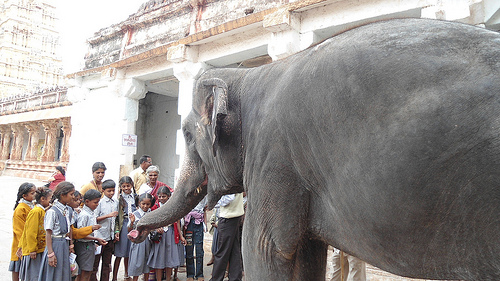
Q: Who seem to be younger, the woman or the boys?
A: The boys are younger than the woman.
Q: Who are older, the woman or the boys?
A: The woman are older than the boys.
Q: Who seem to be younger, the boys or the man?
A: The boys are younger than the man.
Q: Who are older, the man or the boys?
A: The man are older than the boys.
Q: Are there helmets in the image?
A: No, there are no helmets.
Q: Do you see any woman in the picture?
A: Yes, there is a woman.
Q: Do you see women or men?
A: Yes, there is a woman.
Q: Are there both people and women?
A: Yes, there are both a woman and a person.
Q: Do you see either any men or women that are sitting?
A: Yes, the woman is sitting.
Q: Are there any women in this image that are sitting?
A: Yes, there is a woman that is sitting.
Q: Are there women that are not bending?
A: Yes, there is a woman that is sitting.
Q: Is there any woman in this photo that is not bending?
A: Yes, there is a woman that is sitting.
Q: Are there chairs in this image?
A: No, there are no chairs.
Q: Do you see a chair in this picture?
A: No, there are no chairs.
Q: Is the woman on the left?
A: Yes, the woman is on the left of the image.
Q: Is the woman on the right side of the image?
A: No, the woman is on the left of the image.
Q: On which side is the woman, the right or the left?
A: The woman is on the left of the image.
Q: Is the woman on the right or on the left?
A: The woman is on the left of the image.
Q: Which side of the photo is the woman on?
A: The woman is on the left of the image.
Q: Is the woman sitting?
A: Yes, the woman is sitting.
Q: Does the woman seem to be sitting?
A: Yes, the woman is sitting.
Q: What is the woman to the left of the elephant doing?
A: The woman is sitting.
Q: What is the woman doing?
A: The woman is sitting.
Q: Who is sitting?
A: The woman is sitting.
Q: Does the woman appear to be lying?
A: No, the woman is sitting.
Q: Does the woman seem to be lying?
A: No, the woman is sitting.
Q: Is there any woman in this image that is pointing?
A: No, there is a woman but she is sitting.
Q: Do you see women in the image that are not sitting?
A: No, there is a woman but she is sitting.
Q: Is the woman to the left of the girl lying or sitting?
A: The woman is sitting.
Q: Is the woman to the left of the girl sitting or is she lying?
A: The woman is sitting.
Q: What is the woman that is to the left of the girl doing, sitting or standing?
A: The woman is sitting.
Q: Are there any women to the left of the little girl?
A: Yes, there is a woman to the left of the girl.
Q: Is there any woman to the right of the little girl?
A: No, the woman is to the left of the girl.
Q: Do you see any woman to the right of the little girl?
A: No, the woman is to the left of the girl.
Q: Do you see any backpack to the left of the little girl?
A: No, there is a woman to the left of the girl.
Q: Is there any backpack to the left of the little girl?
A: No, there is a woman to the left of the girl.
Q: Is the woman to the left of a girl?
A: Yes, the woman is to the left of a girl.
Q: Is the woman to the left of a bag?
A: No, the woman is to the left of a girl.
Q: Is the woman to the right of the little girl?
A: No, the woman is to the left of the girl.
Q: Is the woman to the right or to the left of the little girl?
A: The woman is to the left of the girl.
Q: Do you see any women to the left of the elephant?
A: Yes, there is a woman to the left of the elephant.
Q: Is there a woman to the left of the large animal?
A: Yes, there is a woman to the left of the elephant.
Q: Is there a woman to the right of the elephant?
A: No, the woman is to the left of the elephant.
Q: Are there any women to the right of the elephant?
A: No, the woman is to the left of the elephant.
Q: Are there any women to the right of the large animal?
A: No, the woman is to the left of the elephant.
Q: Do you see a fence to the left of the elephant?
A: No, there is a woman to the left of the elephant.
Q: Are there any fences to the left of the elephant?
A: No, there is a woman to the left of the elephant.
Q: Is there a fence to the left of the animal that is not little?
A: No, there is a woman to the left of the elephant.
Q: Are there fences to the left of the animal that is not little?
A: No, there is a woman to the left of the elephant.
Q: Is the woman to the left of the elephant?
A: Yes, the woman is to the left of the elephant.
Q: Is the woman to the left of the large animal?
A: Yes, the woman is to the left of the elephant.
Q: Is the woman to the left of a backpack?
A: No, the woman is to the left of the elephant.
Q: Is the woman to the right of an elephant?
A: No, the woman is to the left of an elephant.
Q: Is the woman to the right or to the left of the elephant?
A: The woman is to the left of the elephant.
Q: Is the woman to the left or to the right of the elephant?
A: The woman is to the left of the elephant.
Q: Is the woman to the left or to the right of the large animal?
A: The woman is to the left of the elephant.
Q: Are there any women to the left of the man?
A: Yes, there is a woman to the left of the man.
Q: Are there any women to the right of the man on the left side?
A: No, the woman is to the left of the man.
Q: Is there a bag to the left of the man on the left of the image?
A: No, there is a woman to the left of the man.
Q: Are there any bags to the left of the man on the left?
A: No, there is a woman to the left of the man.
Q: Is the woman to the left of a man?
A: Yes, the woman is to the left of a man.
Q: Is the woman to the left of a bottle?
A: No, the woman is to the left of a man.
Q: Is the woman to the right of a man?
A: No, the woman is to the left of a man.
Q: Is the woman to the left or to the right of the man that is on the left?
A: The woman is to the left of the man.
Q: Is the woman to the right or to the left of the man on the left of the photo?
A: The woman is to the left of the man.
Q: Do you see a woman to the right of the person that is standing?
A: Yes, there is a woman to the right of the person.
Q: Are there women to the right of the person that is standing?
A: Yes, there is a woman to the right of the person.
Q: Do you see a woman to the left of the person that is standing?
A: No, the woman is to the right of the person.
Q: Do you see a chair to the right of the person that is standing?
A: No, there is a woman to the right of the person.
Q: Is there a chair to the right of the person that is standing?
A: No, there is a woman to the right of the person.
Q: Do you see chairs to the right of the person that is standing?
A: No, there is a woman to the right of the person.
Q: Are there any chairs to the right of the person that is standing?
A: No, there is a woman to the right of the person.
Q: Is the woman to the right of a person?
A: Yes, the woman is to the right of a person.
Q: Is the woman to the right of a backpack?
A: No, the woman is to the right of a person.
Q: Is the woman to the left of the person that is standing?
A: No, the woman is to the right of the person.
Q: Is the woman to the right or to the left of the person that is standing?
A: The woman is to the right of the person.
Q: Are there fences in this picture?
A: No, there are no fences.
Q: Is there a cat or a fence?
A: No, there are no fences or cats.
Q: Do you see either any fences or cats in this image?
A: No, there are no fences or cats.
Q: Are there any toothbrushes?
A: No, there are no toothbrushes.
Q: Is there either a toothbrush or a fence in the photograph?
A: No, there are no toothbrushes or fences.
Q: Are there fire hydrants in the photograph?
A: No, there are no fire hydrants.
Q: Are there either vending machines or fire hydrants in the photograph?
A: No, there are no fire hydrants or vending machines.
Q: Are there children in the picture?
A: Yes, there are children.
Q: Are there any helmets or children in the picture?
A: Yes, there are children.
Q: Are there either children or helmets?
A: Yes, there are children.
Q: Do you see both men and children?
A: Yes, there are both children and a man.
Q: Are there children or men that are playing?
A: Yes, the children are playing.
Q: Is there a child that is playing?
A: Yes, there are children that are playing.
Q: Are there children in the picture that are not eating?
A: Yes, there are children that are playing.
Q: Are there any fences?
A: No, there are no fences.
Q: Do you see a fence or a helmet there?
A: No, there are no fences or helmets.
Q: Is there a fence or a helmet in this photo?
A: No, there are no fences or helmets.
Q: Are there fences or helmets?
A: No, there are no fences or helmets.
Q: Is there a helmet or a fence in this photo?
A: No, there are no fences or helmets.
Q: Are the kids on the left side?
A: Yes, the kids are on the left of the image.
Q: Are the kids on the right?
A: No, the kids are on the left of the image.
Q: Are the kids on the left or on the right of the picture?
A: The kids are on the left of the image.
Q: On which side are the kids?
A: The kids are on the left of the image.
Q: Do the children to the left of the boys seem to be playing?
A: Yes, the children are playing.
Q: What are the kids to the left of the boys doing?
A: The kids are playing.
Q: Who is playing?
A: The kids are playing.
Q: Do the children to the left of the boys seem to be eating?
A: No, the children are playing.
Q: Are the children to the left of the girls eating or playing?
A: The children are playing.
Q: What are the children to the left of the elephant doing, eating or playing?
A: The children are playing.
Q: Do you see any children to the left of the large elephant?
A: Yes, there are children to the left of the elephant.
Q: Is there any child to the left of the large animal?
A: Yes, there are children to the left of the elephant.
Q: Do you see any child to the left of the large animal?
A: Yes, there are children to the left of the elephant.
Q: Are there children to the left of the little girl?
A: Yes, there are children to the left of the girl.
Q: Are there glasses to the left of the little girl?
A: No, there are children to the left of the girl.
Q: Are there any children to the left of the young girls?
A: Yes, there are children to the left of the girls.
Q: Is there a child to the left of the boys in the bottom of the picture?
A: Yes, there are children to the left of the boys.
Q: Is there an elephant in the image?
A: Yes, there is an elephant.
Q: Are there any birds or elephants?
A: Yes, there is an elephant.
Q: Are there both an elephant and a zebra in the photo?
A: No, there is an elephant but no zebras.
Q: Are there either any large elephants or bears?
A: Yes, there is a large elephant.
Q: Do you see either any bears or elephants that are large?
A: Yes, the elephant is large.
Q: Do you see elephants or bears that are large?
A: Yes, the elephant is large.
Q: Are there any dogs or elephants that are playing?
A: Yes, the elephant is playing.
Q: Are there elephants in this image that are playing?
A: Yes, there is an elephant that is playing.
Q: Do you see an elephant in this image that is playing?
A: Yes, there is an elephant that is playing.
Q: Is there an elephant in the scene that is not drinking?
A: Yes, there is an elephant that is playing.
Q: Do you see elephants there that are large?
A: Yes, there is a large elephant.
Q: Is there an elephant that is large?
A: Yes, there is an elephant that is large.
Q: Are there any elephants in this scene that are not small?
A: Yes, there is a large elephant.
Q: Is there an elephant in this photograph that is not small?
A: Yes, there is a large elephant.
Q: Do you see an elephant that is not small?
A: Yes, there is a large elephant.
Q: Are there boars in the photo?
A: No, there are no boars.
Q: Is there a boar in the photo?
A: No, there are no boars.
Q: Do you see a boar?
A: No, there are no boars.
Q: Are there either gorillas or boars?
A: No, there are no boars or gorillas.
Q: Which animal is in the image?
A: The animal is an elephant.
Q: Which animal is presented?
A: The animal is an elephant.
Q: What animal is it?
A: The animal is an elephant.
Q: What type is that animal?
A: This is an elephant.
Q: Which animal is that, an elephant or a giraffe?
A: This is an elephant.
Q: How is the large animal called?
A: The animal is an elephant.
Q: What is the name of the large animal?
A: The animal is an elephant.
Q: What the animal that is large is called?
A: The animal is an elephant.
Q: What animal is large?
A: The animal is an elephant.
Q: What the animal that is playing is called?
A: The animal is an elephant.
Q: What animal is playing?
A: The animal is an elephant.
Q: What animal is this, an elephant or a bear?
A: This is an elephant.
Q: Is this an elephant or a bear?
A: This is an elephant.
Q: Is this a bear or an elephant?
A: This is an elephant.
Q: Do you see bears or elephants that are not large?
A: No, there is an elephant but it is large.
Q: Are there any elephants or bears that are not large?
A: No, there is an elephant but it is large.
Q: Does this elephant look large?
A: Yes, the elephant is large.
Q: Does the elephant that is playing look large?
A: Yes, the elephant is large.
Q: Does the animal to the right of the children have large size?
A: Yes, the elephant is large.